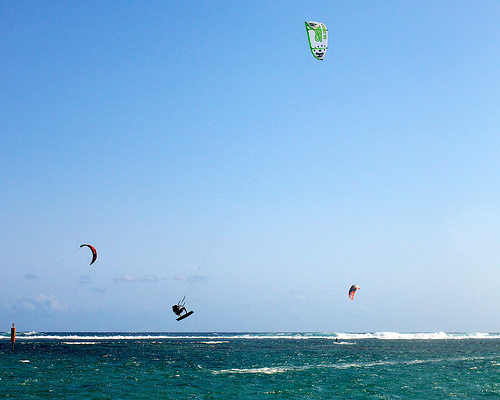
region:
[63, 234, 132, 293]
kite above the ocean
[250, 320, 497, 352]
white surf on the ocean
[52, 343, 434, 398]
ocean is blue and aqua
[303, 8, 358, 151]
green and white kite high in the sky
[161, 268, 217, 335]
surfer in the air over the water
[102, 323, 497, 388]
several waves in the ocean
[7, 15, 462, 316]
clear blue skies over the ocean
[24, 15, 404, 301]
three kites in view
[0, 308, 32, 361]
orange post in the water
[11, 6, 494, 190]
Kite very high in the air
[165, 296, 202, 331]
a skier in the sky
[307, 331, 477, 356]
white ocean waves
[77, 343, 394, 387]
blue ocean waters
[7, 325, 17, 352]
a orange floater in the water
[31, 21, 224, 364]
clear blue skys over the water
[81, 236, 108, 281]
a sail in the air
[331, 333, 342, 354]
a person in the water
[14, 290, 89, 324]
A cloud in the sky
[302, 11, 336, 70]
a white and green black sail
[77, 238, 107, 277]
a red and black sail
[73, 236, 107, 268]
kite in the sky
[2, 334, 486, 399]
dark blue body of water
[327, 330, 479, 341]
wave in the water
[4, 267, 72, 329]
small cloud formation in the sky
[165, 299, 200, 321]
person on a board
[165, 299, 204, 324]
person in the air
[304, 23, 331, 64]
green, white, and black kite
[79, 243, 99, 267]
kite that is folded over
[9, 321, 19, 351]
pole in the water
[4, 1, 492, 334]
mostly clear blue sky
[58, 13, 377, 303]
three kite in the sky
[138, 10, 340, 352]
person who is kite surfing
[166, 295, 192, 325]
kite surfer in mid air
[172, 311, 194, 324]
black board of kite surfer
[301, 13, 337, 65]
green and white kite of kite surfer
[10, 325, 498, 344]
white foam of wave crashing into ocean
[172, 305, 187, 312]
black life vest of kite surfer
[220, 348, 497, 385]
line of white foam in foreground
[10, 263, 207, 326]
clouds close to the horizon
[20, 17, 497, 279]
clear blue sky kites are flying in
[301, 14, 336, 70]
kite in the sky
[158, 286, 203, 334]
person on a board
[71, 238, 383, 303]
two clouds in the sky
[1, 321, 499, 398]
body of water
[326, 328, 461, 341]
wave on the water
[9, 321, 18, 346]
pole sticking out of the water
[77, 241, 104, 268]
cloud that is bent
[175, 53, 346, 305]
thin string of the kite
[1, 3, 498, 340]
clear, bright blue sky